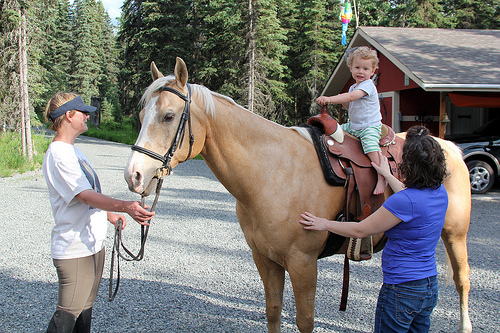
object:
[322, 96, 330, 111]
horn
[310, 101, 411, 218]
saddle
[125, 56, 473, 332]
horse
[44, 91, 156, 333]
woman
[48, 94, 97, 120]
visor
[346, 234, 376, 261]
stirrups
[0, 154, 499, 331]
parking lot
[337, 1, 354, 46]
windsock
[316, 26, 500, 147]
building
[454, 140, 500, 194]
car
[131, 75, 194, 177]
bridle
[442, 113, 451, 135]
dinner bell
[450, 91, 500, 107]
awning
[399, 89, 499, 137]
front porch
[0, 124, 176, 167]
driveway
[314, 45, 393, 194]
child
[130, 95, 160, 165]
design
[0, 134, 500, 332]
gravel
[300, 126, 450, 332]
mom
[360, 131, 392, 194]
leg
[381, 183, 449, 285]
shirt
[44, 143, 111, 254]
shirt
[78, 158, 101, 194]
picture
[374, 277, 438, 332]
jeans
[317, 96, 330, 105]
hand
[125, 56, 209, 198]
head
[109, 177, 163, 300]
reins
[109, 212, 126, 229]
hand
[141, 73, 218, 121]
mane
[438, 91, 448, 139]
column